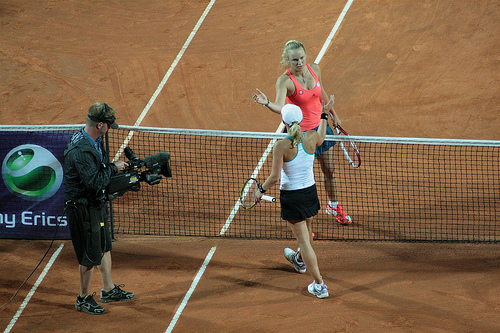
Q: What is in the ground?
A: Net.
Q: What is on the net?
A: Display.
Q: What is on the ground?
A: Line.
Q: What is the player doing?
A: Clapping hand.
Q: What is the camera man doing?
A: Shooting.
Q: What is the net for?
A: Tennis.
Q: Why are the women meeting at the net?
A: It is traditional to shake hands, across the net, after a match.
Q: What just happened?
A: A tennis match was played.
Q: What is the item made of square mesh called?
A: A tennis net.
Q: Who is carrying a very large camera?
A: A man wearing a visor and knee-high shorts.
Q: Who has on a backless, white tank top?
A: The female tennis player, on the nearest side of the tennis net.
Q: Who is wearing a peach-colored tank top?
A: The female tennis player, on the far side of the net.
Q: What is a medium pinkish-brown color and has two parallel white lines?
A: The tennis court.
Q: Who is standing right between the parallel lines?
A: The man with the camera.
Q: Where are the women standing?
A: On the tennis court.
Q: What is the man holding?
A: A camera.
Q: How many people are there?
A: Three.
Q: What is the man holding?
A: A camera.